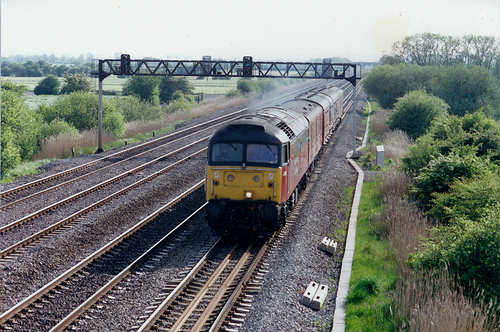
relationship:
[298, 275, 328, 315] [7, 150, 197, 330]
ties near tracks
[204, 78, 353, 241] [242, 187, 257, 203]
train has light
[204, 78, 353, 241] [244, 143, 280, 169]
train has window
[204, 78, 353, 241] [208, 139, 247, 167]
train has window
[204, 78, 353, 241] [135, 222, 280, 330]
train on track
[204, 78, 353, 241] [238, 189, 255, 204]
train has light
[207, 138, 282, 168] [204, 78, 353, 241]
windshield in front of train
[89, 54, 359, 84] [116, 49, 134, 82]
pole with traffic light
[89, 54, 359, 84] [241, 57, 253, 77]
pole with light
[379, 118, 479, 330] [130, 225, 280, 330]
straw in right of tracks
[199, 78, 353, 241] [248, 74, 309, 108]
train has smoke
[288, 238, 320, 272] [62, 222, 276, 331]
gravel side track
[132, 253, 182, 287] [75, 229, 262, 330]
gravel between tracks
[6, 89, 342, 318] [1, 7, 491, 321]
tracks in scene